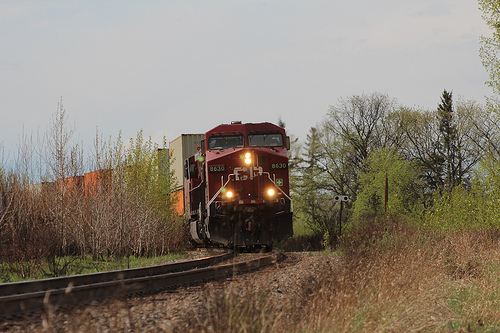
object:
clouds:
[0, 0, 500, 195]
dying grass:
[28, 211, 497, 332]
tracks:
[0, 248, 284, 317]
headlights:
[267, 189, 274, 197]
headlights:
[245, 158, 251, 163]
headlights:
[226, 191, 232, 197]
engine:
[204, 122, 293, 245]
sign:
[276, 179, 284, 187]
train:
[166, 115, 307, 260]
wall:
[306, 87, 361, 164]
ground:
[259, 67, 314, 101]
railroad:
[0, 248, 282, 321]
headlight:
[245, 153, 251, 158]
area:
[0, 246, 499, 332]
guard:
[200, 202, 293, 247]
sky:
[0, 0, 499, 195]